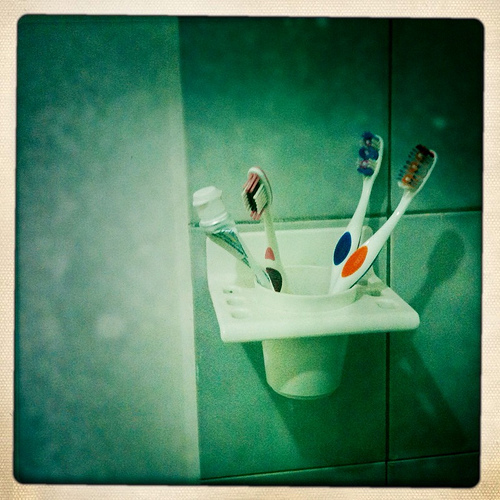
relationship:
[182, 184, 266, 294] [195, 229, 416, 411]
toothpaste in holder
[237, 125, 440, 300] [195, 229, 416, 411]
brushes in holder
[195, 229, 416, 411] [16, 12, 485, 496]
holder on wall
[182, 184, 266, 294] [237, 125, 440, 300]
toothpaste near brushes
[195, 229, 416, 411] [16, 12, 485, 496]
holder in wall